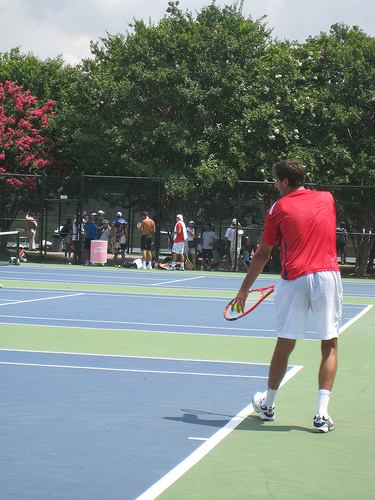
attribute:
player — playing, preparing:
[239, 152, 344, 424]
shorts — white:
[273, 272, 340, 343]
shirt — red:
[266, 190, 341, 277]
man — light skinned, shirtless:
[138, 212, 156, 267]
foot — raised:
[253, 379, 275, 425]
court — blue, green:
[21, 356, 224, 451]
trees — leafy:
[48, 26, 352, 183]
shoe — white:
[253, 388, 275, 418]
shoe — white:
[310, 412, 333, 432]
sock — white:
[264, 387, 278, 407]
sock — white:
[317, 391, 329, 416]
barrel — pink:
[88, 237, 111, 264]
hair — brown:
[272, 160, 308, 186]